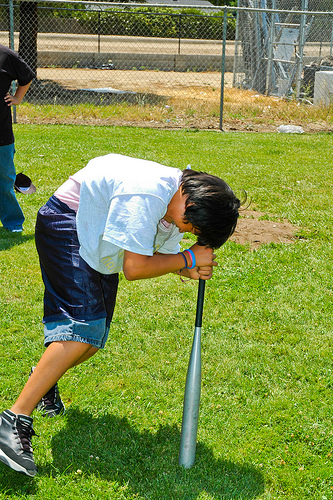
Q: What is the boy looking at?
A: The ground.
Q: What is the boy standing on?
A: Green grass.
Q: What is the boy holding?
A: A silver baseball bat.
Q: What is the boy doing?
A: Spinning on a baseball bat.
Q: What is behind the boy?
A: A fence.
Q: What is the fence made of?
A: Metal.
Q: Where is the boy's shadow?
A: On the ground.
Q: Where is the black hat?
A: On the ground.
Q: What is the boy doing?
A: He is bending over.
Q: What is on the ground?
A: A shadow.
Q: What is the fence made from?
A: Wire mesh.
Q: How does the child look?
A: He is bent over.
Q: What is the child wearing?
A: A pink undershirt.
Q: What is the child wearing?
A: Blue shorts.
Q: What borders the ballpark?
A: A chain link fence.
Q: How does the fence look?
A: It is very green.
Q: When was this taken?
A: During the day.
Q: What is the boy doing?
A: Circling around a baseball bat.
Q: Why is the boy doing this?
A: For a game.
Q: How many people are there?
A: One.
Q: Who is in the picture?
A: A male child.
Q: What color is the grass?
A: Green.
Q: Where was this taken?
A: In a park.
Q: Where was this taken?
A: By the baseball diamond.